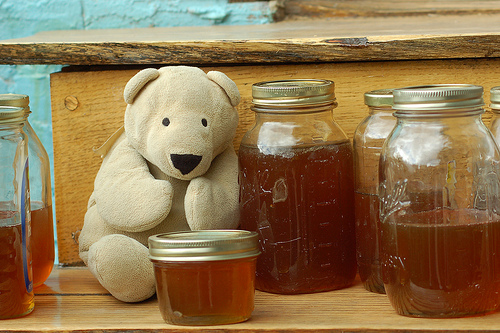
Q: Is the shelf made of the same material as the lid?
A: No, the shelf is made of wood and the lid is made of metal.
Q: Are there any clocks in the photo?
A: No, there are no clocks.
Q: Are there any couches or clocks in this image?
A: No, there are no clocks or couches.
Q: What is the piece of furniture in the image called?
A: The piece of furniture is a shelf.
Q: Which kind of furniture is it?
A: The piece of furniture is a shelf.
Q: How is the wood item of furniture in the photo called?
A: The piece of furniture is a shelf.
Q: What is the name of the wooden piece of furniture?
A: The piece of furniture is a shelf.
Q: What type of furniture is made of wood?
A: The furniture is a shelf.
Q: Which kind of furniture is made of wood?
A: The furniture is a shelf.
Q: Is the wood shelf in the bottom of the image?
A: Yes, the shelf is in the bottom of the image.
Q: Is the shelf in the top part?
A: No, the shelf is in the bottom of the image.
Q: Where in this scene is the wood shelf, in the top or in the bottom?
A: The shelf is in the bottom of the image.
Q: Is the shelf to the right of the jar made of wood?
A: Yes, the shelf is made of wood.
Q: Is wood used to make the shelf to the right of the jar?
A: Yes, the shelf is made of wood.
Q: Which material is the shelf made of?
A: The shelf is made of wood.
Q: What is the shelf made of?
A: The shelf is made of wood.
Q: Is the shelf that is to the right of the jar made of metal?
A: No, the shelf is made of wood.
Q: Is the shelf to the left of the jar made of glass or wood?
A: The shelf is made of wood.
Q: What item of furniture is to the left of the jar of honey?
A: The piece of furniture is a shelf.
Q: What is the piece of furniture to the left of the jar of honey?
A: The piece of furniture is a shelf.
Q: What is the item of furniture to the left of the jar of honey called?
A: The piece of furniture is a shelf.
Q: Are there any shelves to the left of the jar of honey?
A: Yes, there is a shelf to the left of the jar.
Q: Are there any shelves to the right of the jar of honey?
A: No, the shelf is to the left of the jar.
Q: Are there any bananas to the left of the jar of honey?
A: No, there is a shelf to the left of the jar.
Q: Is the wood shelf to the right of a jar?
A: No, the shelf is to the left of a jar.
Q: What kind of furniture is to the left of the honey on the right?
A: The piece of furniture is a shelf.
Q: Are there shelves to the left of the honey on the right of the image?
A: Yes, there is a shelf to the left of the honey.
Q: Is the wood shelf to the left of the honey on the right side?
A: Yes, the shelf is to the left of the honey.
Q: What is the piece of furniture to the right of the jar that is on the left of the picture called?
A: The piece of furniture is a shelf.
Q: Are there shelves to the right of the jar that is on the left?
A: Yes, there is a shelf to the right of the jar.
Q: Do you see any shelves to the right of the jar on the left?
A: Yes, there is a shelf to the right of the jar.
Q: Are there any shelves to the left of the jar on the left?
A: No, the shelf is to the right of the jar.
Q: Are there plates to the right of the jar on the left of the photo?
A: No, there is a shelf to the right of the jar.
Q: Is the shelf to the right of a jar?
A: Yes, the shelf is to the right of a jar.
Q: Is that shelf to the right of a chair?
A: No, the shelf is to the right of a jar.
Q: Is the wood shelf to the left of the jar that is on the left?
A: No, the shelf is to the right of the jar.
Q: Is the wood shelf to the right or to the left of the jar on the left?
A: The shelf is to the right of the jar.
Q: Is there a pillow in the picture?
A: No, there are no pillows.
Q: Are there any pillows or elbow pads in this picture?
A: No, there are no pillows or elbow pads.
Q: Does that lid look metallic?
A: Yes, the lid is metallic.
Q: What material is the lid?
A: The lid is made of metal.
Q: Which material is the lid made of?
A: The lid is made of metal.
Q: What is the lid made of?
A: The lid is made of metal.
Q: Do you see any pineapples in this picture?
A: No, there are no pineapples.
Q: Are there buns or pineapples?
A: No, there are no pineapples or buns.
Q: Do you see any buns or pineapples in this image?
A: No, there are no pineapples or buns.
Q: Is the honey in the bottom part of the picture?
A: Yes, the honey is in the bottom of the image.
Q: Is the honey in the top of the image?
A: No, the honey is in the bottom of the image.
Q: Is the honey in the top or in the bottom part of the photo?
A: The honey is in the bottom of the image.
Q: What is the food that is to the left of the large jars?
A: The food is honey.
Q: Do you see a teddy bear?
A: Yes, there is a teddy bear.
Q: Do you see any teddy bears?
A: Yes, there is a teddy bear.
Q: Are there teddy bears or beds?
A: Yes, there is a teddy bear.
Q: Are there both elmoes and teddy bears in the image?
A: No, there is a teddy bear but no elmoes.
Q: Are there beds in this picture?
A: No, there are no beds.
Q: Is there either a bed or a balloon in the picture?
A: No, there are no beds or balloons.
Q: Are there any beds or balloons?
A: No, there are no beds or balloons.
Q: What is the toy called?
A: The toy is a teddy bear.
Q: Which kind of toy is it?
A: The toy is a teddy bear.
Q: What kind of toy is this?
A: This is a teddy bear.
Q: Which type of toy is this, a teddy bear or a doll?
A: This is a teddy bear.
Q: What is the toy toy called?
A: The toy is a teddy bear.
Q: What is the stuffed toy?
A: The toy is a teddy bear.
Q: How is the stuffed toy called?
A: The toy is a teddy bear.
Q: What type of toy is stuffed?
A: The toy is a teddy bear.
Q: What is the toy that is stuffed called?
A: The toy is a teddy bear.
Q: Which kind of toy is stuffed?
A: The toy is a teddy bear.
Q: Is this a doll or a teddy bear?
A: This is a teddy bear.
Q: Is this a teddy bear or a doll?
A: This is a teddy bear.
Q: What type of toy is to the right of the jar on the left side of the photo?
A: The toy is a teddy bear.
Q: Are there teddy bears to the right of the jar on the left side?
A: Yes, there is a teddy bear to the right of the jar.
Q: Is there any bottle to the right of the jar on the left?
A: No, there is a teddy bear to the right of the jar.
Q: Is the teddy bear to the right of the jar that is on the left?
A: Yes, the teddy bear is to the right of the jar.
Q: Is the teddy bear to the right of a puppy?
A: No, the teddy bear is to the right of the jar.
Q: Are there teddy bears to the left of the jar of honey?
A: Yes, there is a teddy bear to the left of the jar.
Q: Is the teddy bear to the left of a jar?
A: Yes, the teddy bear is to the left of a jar.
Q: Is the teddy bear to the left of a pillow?
A: No, the teddy bear is to the left of a jar.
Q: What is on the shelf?
A: The teddy bear is on the shelf.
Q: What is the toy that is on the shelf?
A: The toy is a teddy bear.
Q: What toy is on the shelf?
A: The toy is a teddy bear.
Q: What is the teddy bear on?
A: The teddy bear is on the shelf.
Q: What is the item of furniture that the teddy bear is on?
A: The piece of furniture is a shelf.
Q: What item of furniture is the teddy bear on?
A: The teddy bear is on the shelf.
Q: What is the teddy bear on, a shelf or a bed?
A: The teddy bear is on a shelf.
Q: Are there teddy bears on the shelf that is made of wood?
A: Yes, there is a teddy bear on the shelf.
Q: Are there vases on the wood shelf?
A: No, there is a teddy bear on the shelf.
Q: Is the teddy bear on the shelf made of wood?
A: Yes, the teddy bear is on the shelf.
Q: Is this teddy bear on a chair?
A: No, the teddy bear is on the shelf.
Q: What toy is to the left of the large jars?
A: The toy is a teddy bear.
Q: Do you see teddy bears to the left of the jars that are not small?
A: Yes, there is a teddy bear to the left of the jars.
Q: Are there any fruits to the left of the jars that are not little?
A: No, there is a teddy bear to the left of the jars.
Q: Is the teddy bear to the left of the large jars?
A: Yes, the teddy bear is to the left of the jars.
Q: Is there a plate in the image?
A: No, there are no plates.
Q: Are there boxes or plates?
A: No, there are no plates or boxes.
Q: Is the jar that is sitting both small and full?
A: Yes, the jar is small and full.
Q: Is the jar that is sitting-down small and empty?
A: No, the jar is small but full.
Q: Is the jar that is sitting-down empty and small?
A: No, the jar is small but full.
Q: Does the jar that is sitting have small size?
A: Yes, the jar is small.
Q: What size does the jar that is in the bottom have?
A: The jar has small size.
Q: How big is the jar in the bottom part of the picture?
A: The jar is small.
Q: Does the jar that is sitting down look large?
A: No, the jar is small.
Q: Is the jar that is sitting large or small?
A: The jar is small.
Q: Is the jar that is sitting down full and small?
A: Yes, the jar is full and small.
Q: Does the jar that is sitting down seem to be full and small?
A: Yes, the jar is full and small.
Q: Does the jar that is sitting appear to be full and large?
A: No, the jar is full but small.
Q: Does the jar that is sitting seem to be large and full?
A: No, the jar is full but small.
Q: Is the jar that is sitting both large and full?
A: No, the jar is full but small.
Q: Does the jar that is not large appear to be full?
A: Yes, the jar is full.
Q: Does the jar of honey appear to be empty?
A: No, the jar is full.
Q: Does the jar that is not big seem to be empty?
A: No, the jar is full.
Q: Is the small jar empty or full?
A: The jar is full.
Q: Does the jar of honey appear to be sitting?
A: Yes, the jar is sitting.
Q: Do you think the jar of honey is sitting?
A: Yes, the jar is sitting.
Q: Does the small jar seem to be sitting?
A: Yes, the jar is sitting.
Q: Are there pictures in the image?
A: No, there are no pictures.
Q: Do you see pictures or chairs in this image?
A: No, there are no pictures or chairs.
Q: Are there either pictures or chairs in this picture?
A: No, there are no pictures or chairs.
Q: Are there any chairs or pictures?
A: No, there are no pictures or chairs.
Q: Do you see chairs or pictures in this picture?
A: No, there are no pictures or chairs.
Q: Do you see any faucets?
A: No, there are no faucets.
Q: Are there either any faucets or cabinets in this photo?
A: No, there are no faucets or cabinets.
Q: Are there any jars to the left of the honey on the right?
A: Yes, there are jars to the left of the honey.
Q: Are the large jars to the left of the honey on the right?
A: Yes, the jars are to the left of the honey.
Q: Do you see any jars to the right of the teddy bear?
A: Yes, there are jars to the right of the teddy bear.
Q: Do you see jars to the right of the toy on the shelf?
A: Yes, there are jars to the right of the teddy bear.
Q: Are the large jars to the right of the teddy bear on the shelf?
A: Yes, the jars are to the right of the teddy bear.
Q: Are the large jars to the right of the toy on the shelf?
A: Yes, the jars are to the right of the teddy bear.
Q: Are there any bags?
A: No, there are no bags.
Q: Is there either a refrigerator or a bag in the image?
A: No, there are no bags or refrigerators.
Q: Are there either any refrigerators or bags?
A: No, there are no bags or refrigerators.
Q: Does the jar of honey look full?
A: Yes, the jar is full.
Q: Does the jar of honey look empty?
A: No, the jar is full.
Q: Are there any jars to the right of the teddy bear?
A: Yes, there is a jar to the right of the teddy bear.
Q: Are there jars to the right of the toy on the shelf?
A: Yes, there is a jar to the right of the teddy bear.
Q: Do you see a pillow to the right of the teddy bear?
A: No, there is a jar to the right of the teddy bear.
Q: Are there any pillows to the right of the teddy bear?
A: No, there is a jar to the right of the teddy bear.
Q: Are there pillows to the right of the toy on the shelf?
A: No, there is a jar to the right of the teddy bear.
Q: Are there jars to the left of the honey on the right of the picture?
A: Yes, there is a jar to the left of the honey.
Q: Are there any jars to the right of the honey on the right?
A: No, the jar is to the left of the honey.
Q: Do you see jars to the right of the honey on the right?
A: No, the jar is to the left of the honey.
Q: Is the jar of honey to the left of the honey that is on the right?
A: Yes, the jar is to the left of the honey.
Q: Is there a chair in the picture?
A: No, there are no chairs.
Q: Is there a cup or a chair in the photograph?
A: No, there are no chairs or cups.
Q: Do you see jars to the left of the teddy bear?
A: Yes, there is a jar to the left of the teddy bear.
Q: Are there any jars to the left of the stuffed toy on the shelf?
A: Yes, there is a jar to the left of the teddy bear.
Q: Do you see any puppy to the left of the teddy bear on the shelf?
A: No, there is a jar to the left of the teddy bear.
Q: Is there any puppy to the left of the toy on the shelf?
A: No, there is a jar to the left of the teddy bear.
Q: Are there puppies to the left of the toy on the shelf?
A: No, there is a jar to the left of the teddy bear.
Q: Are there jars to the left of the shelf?
A: Yes, there is a jar to the left of the shelf.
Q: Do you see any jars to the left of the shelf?
A: Yes, there is a jar to the left of the shelf.